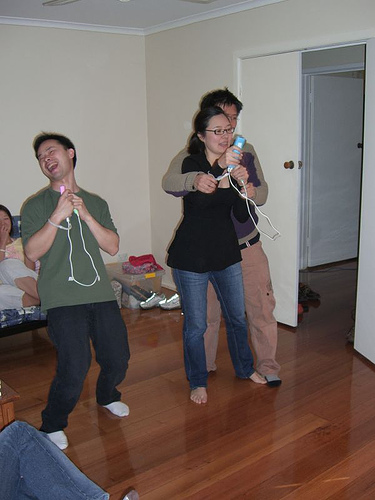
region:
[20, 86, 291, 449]
People holding game controls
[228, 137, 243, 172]
Blue colored game control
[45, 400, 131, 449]
A pair of white socks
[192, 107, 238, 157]
A woman wearing eye glasses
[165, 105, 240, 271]
Woman in a black top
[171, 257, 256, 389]
Woman in blue jeans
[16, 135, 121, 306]
Man in a green t-shirt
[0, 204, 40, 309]
Woman sitting on a couch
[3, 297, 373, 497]
Brown floor made of wood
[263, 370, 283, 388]
Gray and black sock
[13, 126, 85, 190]
head of a person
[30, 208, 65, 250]
arm of a person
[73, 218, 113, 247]
arm of a person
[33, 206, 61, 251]
an arm of a person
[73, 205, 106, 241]
am arm of a person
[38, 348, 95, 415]
leg of a person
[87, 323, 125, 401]
leg of a person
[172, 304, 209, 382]
leg of a person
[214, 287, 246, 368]
leg of a person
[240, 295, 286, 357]
leg of a person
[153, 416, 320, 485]
the floor is woooden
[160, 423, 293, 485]
the floor is polished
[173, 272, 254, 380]
the jeans are blue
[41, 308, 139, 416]
the jeans are black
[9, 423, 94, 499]
the jeans are blue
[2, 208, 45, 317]
the woman is sitted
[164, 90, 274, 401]
the woman has glasses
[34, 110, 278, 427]
the two are playing wii game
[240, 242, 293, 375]
the pants are brown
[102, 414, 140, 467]
shadow reflection is on the floor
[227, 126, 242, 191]
wii remote in hands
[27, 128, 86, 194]
man laughing eyes closed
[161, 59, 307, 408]
man and women playing will game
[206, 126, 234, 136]
glasses on women s face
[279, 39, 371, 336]
open doorway with door handle left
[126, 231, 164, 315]
bag and a shoe with reflector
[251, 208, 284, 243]
white wire tangled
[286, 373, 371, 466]
wood floor polished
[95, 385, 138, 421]
white sock with long pants over sock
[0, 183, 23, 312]
girl Asian with watch on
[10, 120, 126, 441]
this is a man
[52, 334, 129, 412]
these are the legs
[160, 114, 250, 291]
this is a lady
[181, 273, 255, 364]
the legs are apart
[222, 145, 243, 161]
this is the hand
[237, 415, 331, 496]
this is the floor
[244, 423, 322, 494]
the floor is wooden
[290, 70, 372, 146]
the door is open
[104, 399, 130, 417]
this is the foot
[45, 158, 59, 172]
the man is smiling